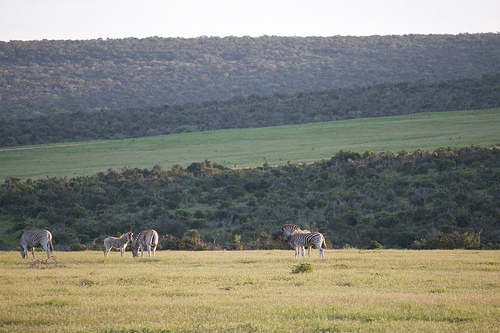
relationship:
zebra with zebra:
[128, 228, 160, 259] [98, 230, 135, 257]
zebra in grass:
[128, 228, 160, 259] [1, 247, 497, 331]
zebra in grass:
[98, 230, 135, 257] [1, 247, 497, 331]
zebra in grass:
[17, 224, 57, 263] [1, 247, 497, 331]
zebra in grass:
[278, 217, 328, 260] [1, 247, 497, 331]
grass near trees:
[1, 247, 497, 331] [0, 148, 499, 251]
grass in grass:
[1, 247, 497, 331] [1, 247, 497, 331]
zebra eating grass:
[128, 228, 160, 259] [1, 247, 497, 331]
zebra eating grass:
[17, 224, 57, 263] [1, 247, 497, 331]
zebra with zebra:
[98, 230, 135, 257] [128, 228, 160, 259]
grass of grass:
[1, 247, 497, 331] [1, 247, 497, 331]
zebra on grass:
[278, 217, 328, 260] [1, 247, 497, 331]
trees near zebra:
[0, 148, 499, 251] [128, 228, 160, 259]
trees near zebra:
[0, 148, 499, 251] [98, 230, 135, 257]